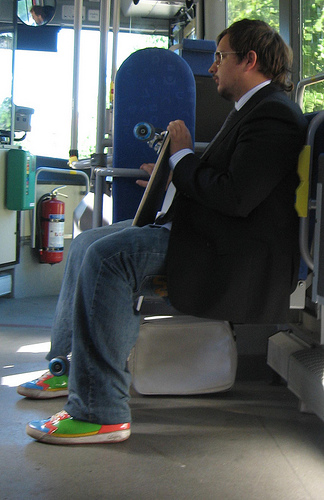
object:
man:
[16, 17, 310, 447]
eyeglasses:
[214, 50, 247, 67]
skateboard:
[48, 121, 174, 376]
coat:
[163, 80, 307, 325]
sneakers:
[25, 408, 133, 447]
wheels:
[132, 121, 154, 141]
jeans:
[44, 219, 171, 426]